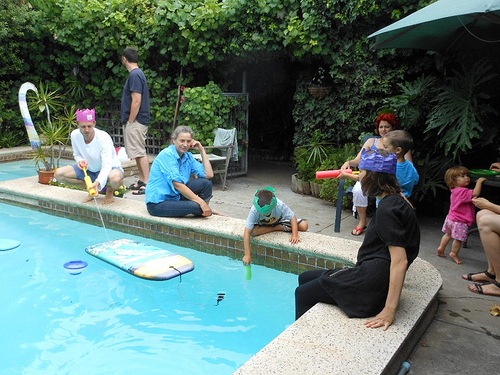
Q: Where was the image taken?
A: It was taken at the swimming pool.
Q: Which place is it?
A: It is a swimming pool.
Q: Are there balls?
A: No, there are no balls.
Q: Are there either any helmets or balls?
A: No, there are no balls or helmets.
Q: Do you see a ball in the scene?
A: No, there are no balls.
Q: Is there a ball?
A: No, there are no balls.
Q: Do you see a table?
A: Yes, there is a table.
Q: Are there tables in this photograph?
A: Yes, there is a table.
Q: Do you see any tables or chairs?
A: Yes, there is a table.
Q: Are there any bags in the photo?
A: No, there are no bags.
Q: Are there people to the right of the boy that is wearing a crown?
A: Yes, there is a person to the right of the boy.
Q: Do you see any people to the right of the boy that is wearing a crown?
A: Yes, there is a person to the right of the boy.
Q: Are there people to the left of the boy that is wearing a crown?
A: No, the person is to the right of the boy.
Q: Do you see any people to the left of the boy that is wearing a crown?
A: No, the person is to the right of the boy.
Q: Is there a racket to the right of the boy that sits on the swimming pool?
A: No, there is a person to the right of the boy.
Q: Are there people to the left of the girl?
A: Yes, there is a person to the left of the girl.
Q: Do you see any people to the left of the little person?
A: Yes, there is a person to the left of the girl.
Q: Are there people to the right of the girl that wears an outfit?
A: No, the person is to the left of the girl.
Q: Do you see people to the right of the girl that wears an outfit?
A: No, the person is to the left of the girl.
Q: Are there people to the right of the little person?
A: No, the person is to the left of the girl.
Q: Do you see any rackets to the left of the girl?
A: No, there is a person to the left of the girl.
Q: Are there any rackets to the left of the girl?
A: No, there is a person to the left of the girl.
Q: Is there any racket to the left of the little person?
A: No, there is a person to the left of the girl.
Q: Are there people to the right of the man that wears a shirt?
A: Yes, there is a person to the right of the man.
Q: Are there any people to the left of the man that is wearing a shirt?
A: No, the person is to the right of the man.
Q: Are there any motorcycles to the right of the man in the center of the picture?
A: No, there is a person to the right of the man.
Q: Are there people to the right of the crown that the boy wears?
A: Yes, there is a person to the right of the crown.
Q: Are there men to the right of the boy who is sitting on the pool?
A: Yes, there is a man to the right of the boy.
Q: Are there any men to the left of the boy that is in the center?
A: No, the man is to the right of the boy.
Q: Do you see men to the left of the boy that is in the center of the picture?
A: No, the man is to the right of the boy.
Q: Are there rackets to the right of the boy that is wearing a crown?
A: No, there is a man to the right of the boy.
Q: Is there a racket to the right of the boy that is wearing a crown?
A: No, there is a man to the right of the boy.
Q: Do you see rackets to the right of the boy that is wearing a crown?
A: No, there is a man to the right of the boy.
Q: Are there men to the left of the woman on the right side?
A: Yes, there is a man to the left of the woman.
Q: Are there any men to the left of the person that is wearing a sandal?
A: Yes, there is a man to the left of the woman.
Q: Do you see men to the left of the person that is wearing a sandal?
A: Yes, there is a man to the left of the woman.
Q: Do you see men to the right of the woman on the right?
A: No, the man is to the left of the woman.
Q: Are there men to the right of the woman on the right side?
A: No, the man is to the left of the woman.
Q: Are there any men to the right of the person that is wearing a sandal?
A: No, the man is to the left of the woman.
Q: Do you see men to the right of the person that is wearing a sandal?
A: No, the man is to the left of the woman.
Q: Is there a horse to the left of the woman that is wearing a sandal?
A: No, there is a man to the left of the woman.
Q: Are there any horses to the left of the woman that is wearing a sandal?
A: No, there is a man to the left of the woman.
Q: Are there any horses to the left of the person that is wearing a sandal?
A: No, there is a man to the left of the woman.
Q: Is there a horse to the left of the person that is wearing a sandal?
A: No, there is a man to the left of the woman.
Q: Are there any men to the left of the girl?
A: Yes, there is a man to the left of the girl.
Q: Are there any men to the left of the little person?
A: Yes, there is a man to the left of the girl.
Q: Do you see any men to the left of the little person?
A: Yes, there is a man to the left of the girl.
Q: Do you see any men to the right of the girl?
A: No, the man is to the left of the girl.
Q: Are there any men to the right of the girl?
A: No, the man is to the left of the girl.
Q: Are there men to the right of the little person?
A: No, the man is to the left of the girl.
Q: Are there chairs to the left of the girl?
A: No, there is a man to the left of the girl.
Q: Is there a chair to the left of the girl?
A: No, there is a man to the left of the girl.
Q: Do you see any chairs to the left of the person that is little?
A: No, there is a man to the left of the girl.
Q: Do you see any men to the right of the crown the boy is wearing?
A: Yes, there is a man to the right of the crown.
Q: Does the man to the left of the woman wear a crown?
A: Yes, the man wears a crown.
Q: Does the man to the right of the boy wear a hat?
A: No, the man wears a crown.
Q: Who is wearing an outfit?
A: The man is wearing an outfit.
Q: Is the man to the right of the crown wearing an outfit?
A: Yes, the man is wearing an outfit.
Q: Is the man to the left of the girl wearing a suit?
A: No, the man is wearing an outfit.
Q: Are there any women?
A: Yes, there is a woman.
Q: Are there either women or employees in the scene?
A: Yes, there is a woman.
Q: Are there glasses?
A: No, there are no glasses.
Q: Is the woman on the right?
A: Yes, the woman is on the right of the image.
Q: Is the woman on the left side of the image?
A: No, the woman is on the right of the image.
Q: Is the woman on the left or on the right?
A: The woman is on the right of the image.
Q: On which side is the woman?
A: The woman is on the right of the image.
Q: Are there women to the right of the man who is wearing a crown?
A: Yes, there is a woman to the right of the man.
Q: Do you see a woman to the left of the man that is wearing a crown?
A: No, the woman is to the right of the man.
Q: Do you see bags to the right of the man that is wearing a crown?
A: No, there is a woman to the right of the man.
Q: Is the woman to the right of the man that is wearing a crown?
A: Yes, the woman is to the right of the man.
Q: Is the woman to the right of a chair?
A: No, the woman is to the right of the man.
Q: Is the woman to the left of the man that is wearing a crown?
A: No, the woman is to the right of the man.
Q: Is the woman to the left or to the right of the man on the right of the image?
A: The woman is to the right of the man.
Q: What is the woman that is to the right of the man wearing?
A: The woman is wearing a sandal.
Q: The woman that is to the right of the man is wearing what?
A: The woman is wearing a sandal.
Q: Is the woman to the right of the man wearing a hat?
A: No, the woman is wearing a sandal.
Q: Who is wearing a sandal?
A: The woman is wearing a sandal.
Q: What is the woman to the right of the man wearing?
A: The woman is wearing a sandal.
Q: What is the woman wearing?
A: The woman is wearing a sandal.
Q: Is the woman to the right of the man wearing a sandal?
A: Yes, the woman is wearing a sandal.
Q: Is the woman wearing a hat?
A: No, the woman is wearing a sandal.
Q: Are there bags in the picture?
A: No, there are no bags.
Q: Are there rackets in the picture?
A: No, there are no rackets.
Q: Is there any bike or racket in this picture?
A: No, there are no rackets or bikes.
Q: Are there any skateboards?
A: No, there are no skateboards.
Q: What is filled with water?
A: The swimming pool is filled with water.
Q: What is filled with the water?
A: The swimming pool is filled with water.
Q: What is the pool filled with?
A: The pool is filled with water.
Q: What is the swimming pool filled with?
A: The pool is filled with water.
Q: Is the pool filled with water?
A: Yes, the pool is filled with water.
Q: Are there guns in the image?
A: Yes, there is a gun.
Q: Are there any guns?
A: Yes, there is a gun.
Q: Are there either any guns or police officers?
A: Yes, there is a gun.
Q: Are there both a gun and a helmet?
A: No, there is a gun but no helmets.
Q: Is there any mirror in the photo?
A: No, there are no mirrors.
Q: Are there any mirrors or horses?
A: No, there are no mirrors or horses.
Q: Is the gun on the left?
A: Yes, the gun is on the left of the image.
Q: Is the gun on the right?
A: No, the gun is on the left of the image.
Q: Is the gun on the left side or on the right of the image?
A: The gun is on the left of the image.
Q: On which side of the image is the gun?
A: The gun is on the left of the image.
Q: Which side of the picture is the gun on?
A: The gun is on the left of the image.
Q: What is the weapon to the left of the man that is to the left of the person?
A: The weapon is a gun.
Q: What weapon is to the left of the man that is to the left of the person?
A: The weapon is a gun.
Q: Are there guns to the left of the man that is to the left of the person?
A: Yes, there is a gun to the left of the man.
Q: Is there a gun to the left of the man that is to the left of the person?
A: Yes, there is a gun to the left of the man.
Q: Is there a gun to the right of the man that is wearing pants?
A: No, the gun is to the left of the man.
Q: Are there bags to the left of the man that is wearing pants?
A: No, there is a gun to the left of the man.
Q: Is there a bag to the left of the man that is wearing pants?
A: No, there is a gun to the left of the man.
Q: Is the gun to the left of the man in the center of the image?
A: Yes, the gun is to the left of the man.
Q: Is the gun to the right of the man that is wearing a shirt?
A: No, the gun is to the left of the man.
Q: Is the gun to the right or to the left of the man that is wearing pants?
A: The gun is to the left of the man.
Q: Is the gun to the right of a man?
A: No, the gun is to the left of a man.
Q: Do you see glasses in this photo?
A: No, there are no glasses.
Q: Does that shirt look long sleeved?
A: Yes, the shirt is long sleeved.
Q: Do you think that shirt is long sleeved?
A: Yes, the shirt is long sleeved.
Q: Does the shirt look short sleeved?
A: No, the shirt is long sleeved.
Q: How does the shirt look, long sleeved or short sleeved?
A: The shirt is long sleeved.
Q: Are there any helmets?
A: No, there are no helmets.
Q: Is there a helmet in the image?
A: No, there are no helmets.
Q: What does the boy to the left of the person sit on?
A: The boy sits on the pool.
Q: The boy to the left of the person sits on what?
A: The boy sits on the pool.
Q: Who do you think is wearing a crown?
A: The boy is wearing a crown.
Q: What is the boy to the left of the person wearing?
A: The boy is wearing a crown.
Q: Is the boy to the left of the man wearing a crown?
A: Yes, the boy is wearing a crown.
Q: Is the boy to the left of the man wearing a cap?
A: No, the boy is wearing a crown.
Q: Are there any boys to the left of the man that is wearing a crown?
A: Yes, there is a boy to the left of the man.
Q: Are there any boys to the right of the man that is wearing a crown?
A: No, the boy is to the left of the man.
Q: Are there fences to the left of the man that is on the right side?
A: No, there is a boy to the left of the man.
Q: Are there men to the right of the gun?
A: Yes, there is a man to the right of the gun.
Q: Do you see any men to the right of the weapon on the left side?
A: Yes, there is a man to the right of the gun.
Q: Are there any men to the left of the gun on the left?
A: No, the man is to the right of the gun.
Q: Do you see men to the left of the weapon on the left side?
A: No, the man is to the right of the gun.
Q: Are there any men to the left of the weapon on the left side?
A: No, the man is to the right of the gun.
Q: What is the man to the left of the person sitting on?
A: The man is sitting on the swimming pool.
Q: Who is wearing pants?
A: The man is wearing pants.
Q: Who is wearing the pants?
A: The man is wearing pants.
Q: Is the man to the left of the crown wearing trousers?
A: Yes, the man is wearing trousers.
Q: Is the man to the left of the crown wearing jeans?
A: No, the man is wearing trousers.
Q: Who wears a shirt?
A: The man wears a shirt.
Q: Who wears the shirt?
A: The man wears a shirt.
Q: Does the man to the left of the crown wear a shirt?
A: Yes, the man wears a shirt.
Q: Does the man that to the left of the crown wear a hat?
A: No, the man wears a shirt.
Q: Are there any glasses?
A: No, there are no glasses.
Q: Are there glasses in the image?
A: No, there are no glasses.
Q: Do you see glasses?
A: No, there are no glasses.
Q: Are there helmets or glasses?
A: No, there are no glasses or helmets.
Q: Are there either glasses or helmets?
A: No, there are no glasses or helmets.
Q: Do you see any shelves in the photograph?
A: No, there are no shelves.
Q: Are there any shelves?
A: No, there are no shelves.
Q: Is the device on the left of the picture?
A: Yes, the device is on the left of the image.